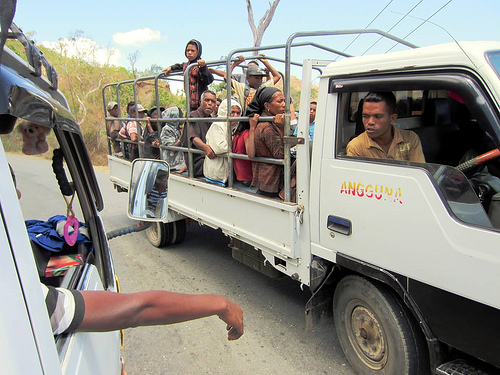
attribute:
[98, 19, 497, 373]
truck — white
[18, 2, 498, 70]
sky — blue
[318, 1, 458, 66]
three wires — suspended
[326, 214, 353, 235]
door handle — black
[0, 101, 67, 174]
bear — tan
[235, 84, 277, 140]
scarf — black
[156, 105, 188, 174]
person — seated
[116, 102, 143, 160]
person — seated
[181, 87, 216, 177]
person — seated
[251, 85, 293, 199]
person — seated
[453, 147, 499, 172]
steering wheel — red, gray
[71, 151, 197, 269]
mirror — barely visible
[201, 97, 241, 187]
person — seated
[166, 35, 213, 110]
jacket — hooded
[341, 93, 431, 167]
person — looking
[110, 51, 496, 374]
truck — white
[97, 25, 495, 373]
vehicle — white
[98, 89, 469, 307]
truck — white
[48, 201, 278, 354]
arm — restingq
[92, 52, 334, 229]
ribs — metal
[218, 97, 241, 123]
hood — white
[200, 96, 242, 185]
jacket — white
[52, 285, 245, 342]
arm — right arm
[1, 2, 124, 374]
vehicle — white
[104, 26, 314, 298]
back — long